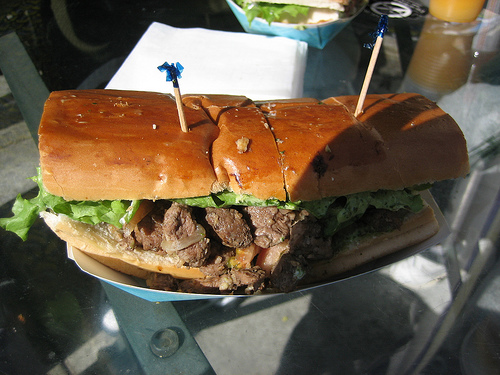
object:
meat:
[160, 201, 210, 267]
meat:
[207, 205, 254, 247]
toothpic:
[350, 10, 383, 117]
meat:
[213, 267, 262, 292]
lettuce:
[183, 193, 266, 219]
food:
[36, 86, 470, 295]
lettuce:
[342, 194, 423, 224]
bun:
[34, 201, 438, 287]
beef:
[249, 208, 285, 245]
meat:
[123, 218, 166, 256]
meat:
[294, 214, 342, 249]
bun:
[27, 77, 466, 206]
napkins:
[223, 37, 285, 64]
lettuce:
[3, 185, 113, 238]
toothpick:
[156, 61, 192, 136]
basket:
[53, 187, 449, 311]